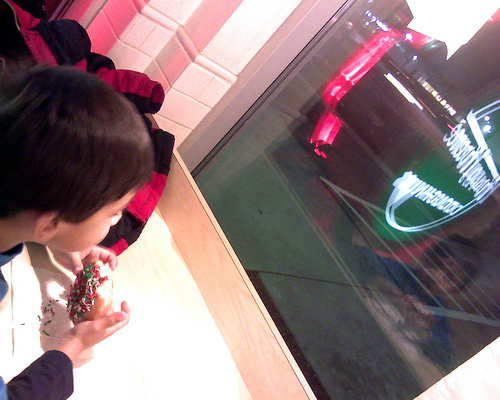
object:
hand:
[62, 301, 130, 348]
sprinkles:
[37, 299, 57, 337]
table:
[24, 248, 250, 400]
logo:
[382, 98, 500, 233]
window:
[188, 0, 499, 400]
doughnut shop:
[0, 0, 499, 400]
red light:
[310, 30, 432, 159]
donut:
[66, 260, 114, 326]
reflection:
[308, 0, 499, 327]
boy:
[0, 67, 154, 400]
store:
[387, 26, 447, 82]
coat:
[0, 0, 174, 256]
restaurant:
[380, 63, 466, 142]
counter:
[111, 114, 314, 400]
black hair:
[0, 65, 155, 224]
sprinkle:
[64, 261, 99, 325]